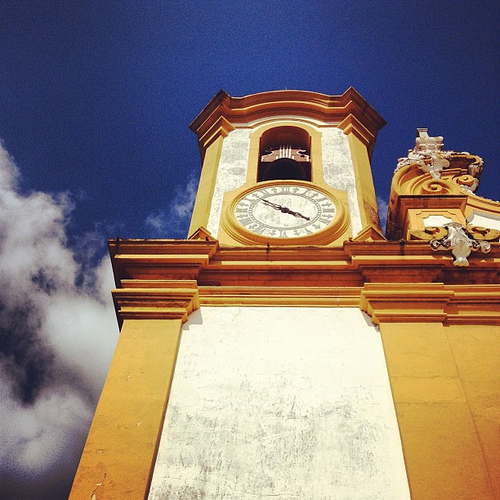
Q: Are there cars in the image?
A: No, there are no cars.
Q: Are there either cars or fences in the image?
A: No, there are no cars or fences.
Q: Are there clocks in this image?
A: Yes, there is a clock.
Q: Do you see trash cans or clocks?
A: Yes, there is a clock.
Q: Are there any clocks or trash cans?
A: Yes, there is a clock.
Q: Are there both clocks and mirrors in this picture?
A: No, there is a clock but no mirrors.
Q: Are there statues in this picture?
A: No, there are no statues.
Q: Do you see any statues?
A: No, there are no statues.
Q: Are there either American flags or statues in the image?
A: No, there are no statues or American flags.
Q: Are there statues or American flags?
A: No, there are no statues or American flags.